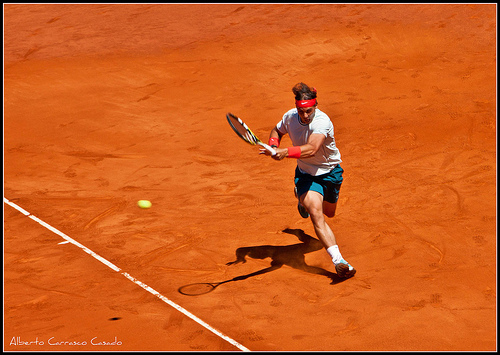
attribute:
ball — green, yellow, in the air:
[138, 197, 151, 210]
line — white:
[5, 197, 248, 350]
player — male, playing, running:
[258, 82, 357, 276]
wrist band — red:
[286, 145, 301, 159]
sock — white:
[325, 244, 347, 264]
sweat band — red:
[294, 97, 316, 107]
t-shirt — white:
[275, 108, 342, 175]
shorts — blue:
[294, 164, 344, 203]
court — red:
[4, 3, 499, 350]